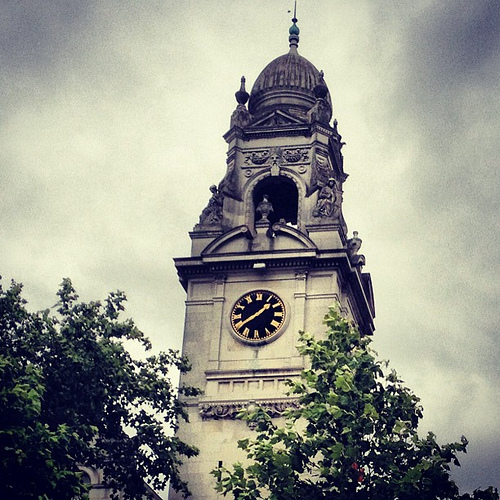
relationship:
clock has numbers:
[229, 289, 289, 346] [232, 295, 281, 342]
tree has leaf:
[211, 299, 499, 500] [333, 376, 345, 390]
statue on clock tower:
[316, 176, 338, 216] [168, 1, 376, 499]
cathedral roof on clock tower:
[248, 0, 333, 124] [168, 1, 376, 499]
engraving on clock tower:
[243, 144, 314, 179] [168, 1, 376, 499]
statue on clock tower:
[199, 184, 222, 225] [168, 1, 376, 499]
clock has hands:
[229, 289, 289, 346] [236, 301, 270, 327]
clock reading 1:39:
[229, 289, 289, 346] [232, 295, 281, 339]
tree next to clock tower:
[211, 299, 499, 500] [168, 1, 376, 499]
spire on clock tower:
[289, 2, 300, 54] [168, 1, 376, 499]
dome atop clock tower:
[250, 51, 332, 102] [168, 1, 376, 499]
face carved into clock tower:
[268, 152, 283, 168] [168, 1, 376, 499]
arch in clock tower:
[249, 171, 299, 231] [168, 1, 376, 499]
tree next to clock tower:
[1, 275, 206, 500] [168, 1, 376, 499]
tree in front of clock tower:
[211, 299, 499, 500] [168, 1, 376, 499]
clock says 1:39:
[229, 289, 289, 346] [232, 292, 284, 338]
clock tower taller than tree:
[168, 1, 376, 499] [211, 299, 499, 500]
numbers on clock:
[232, 295, 281, 342] [229, 289, 289, 346]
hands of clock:
[236, 301, 270, 327] [229, 289, 289, 346]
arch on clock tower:
[249, 171, 299, 231] [168, 1, 376, 499]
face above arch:
[268, 152, 283, 168] [249, 171, 299, 231]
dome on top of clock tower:
[250, 51, 332, 102] [168, 1, 376, 499]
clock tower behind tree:
[168, 1, 376, 499] [211, 299, 499, 500]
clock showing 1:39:
[229, 289, 289, 346] [232, 292, 284, 338]